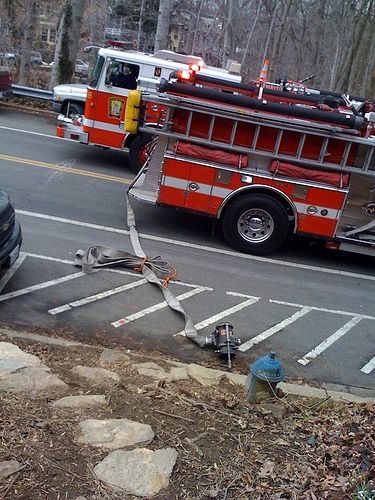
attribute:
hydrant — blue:
[245, 349, 289, 409]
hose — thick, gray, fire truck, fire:
[72, 144, 210, 350]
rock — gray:
[89, 445, 177, 498]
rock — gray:
[73, 415, 153, 449]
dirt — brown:
[1, 333, 371, 499]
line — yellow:
[1, 153, 133, 185]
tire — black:
[217, 192, 290, 258]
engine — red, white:
[121, 67, 371, 257]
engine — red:
[55, 41, 375, 177]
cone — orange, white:
[258, 56, 271, 85]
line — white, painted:
[10, 205, 374, 280]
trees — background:
[1, 2, 374, 110]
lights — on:
[175, 62, 207, 81]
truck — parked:
[48, 79, 93, 124]